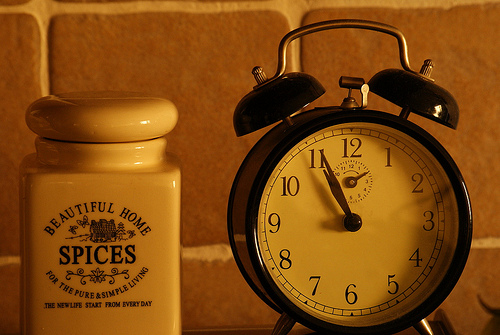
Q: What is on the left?
A: A jar.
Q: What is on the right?
A: Alarm clock.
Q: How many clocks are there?
A: One.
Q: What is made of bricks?
A: The wall.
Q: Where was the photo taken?
A: In a kitchen.